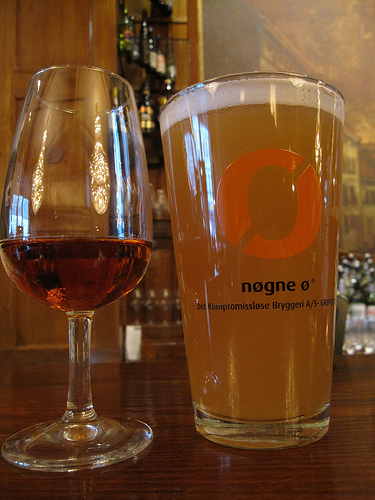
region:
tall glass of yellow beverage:
[151, 64, 356, 458]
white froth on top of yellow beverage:
[155, 71, 348, 131]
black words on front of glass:
[188, 268, 338, 322]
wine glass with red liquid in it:
[2, 63, 159, 473]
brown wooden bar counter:
[4, 342, 374, 498]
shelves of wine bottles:
[111, 1, 192, 182]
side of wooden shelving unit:
[1, 1, 123, 361]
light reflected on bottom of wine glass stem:
[60, 419, 105, 449]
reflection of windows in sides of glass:
[170, 116, 238, 292]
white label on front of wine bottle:
[144, 46, 159, 66]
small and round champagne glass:
[8, 94, 163, 457]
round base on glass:
[14, 413, 135, 477]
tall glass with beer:
[137, 19, 344, 435]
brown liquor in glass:
[18, 230, 135, 310]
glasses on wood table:
[41, 356, 342, 496]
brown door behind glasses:
[1, 4, 173, 364]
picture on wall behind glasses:
[194, 9, 368, 212]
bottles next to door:
[119, 1, 181, 151]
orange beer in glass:
[169, 135, 327, 428]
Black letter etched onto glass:
[235, 277, 251, 294]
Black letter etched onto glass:
[251, 279, 262, 297]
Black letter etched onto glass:
[263, 277, 278, 298]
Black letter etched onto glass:
[275, 277, 286, 292]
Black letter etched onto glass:
[285, 277, 297, 293]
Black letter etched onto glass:
[297, 271, 313, 292]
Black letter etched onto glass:
[187, 295, 212, 312]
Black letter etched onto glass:
[303, 298, 339, 311]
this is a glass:
[3, 60, 154, 473]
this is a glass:
[160, 58, 346, 446]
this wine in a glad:
[171, 298, 258, 394]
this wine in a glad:
[175, 182, 259, 285]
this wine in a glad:
[229, 144, 320, 255]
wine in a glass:
[1, 50, 169, 457]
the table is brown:
[133, 432, 293, 494]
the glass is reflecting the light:
[66, 100, 147, 230]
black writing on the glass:
[177, 268, 332, 330]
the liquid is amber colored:
[0, 204, 147, 318]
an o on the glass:
[172, 115, 337, 269]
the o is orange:
[195, 132, 330, 265]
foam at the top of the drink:
[147, 70, 348, 127]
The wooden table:
[5, 336, 373, 489]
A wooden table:
[7, 339, 371, 497]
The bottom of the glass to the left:
[9, 338, 162, 486]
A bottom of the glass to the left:
[5, 337, 160, 487]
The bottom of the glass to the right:
[173, 339, 339, 464]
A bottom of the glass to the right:
[171, 336, 341, 457]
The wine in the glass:
[1, 236, 151, 312]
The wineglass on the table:
[1, 63, 159, 472]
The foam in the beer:
[159, 78, 345, 138]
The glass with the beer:
[156, 70, 345, 448]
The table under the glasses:
[0, 353, 373, 498]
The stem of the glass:
[63, 309, 93, 418]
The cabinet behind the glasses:
[120, 0, 195, 359]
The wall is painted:
[199, 1, 373, 248]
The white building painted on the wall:
[342, 130, 363, 249]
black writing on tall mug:
[191, 271, 346, 316]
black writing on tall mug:
[185, 269, 343, 316]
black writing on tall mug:
[189, 271, 350, 317]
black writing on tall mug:
[184, 270, 347, 322]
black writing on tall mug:
[187, 268, 338, 324]